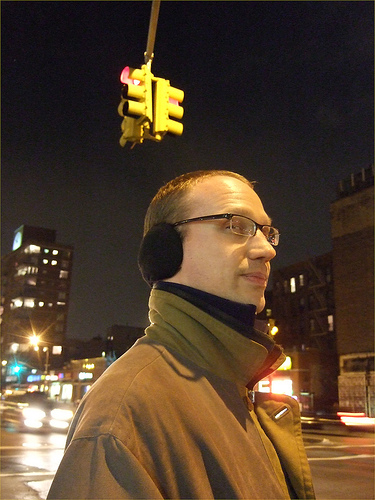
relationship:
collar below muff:
[153, 292, 267, 385] [139, 223, 184, 281]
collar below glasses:
[153, 292, 267, 385] [169, 214, 281, 248]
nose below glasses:
[250, 230, 275, 261] [169, 214, 281, 248]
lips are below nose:
[245, 267, 267, 286] [250, 230, 275, 261]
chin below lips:
[243, 292, 270, 311] [245, 267, 267, 286]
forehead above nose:
[193, 179, 271, 220] [250, 230, 275, 261]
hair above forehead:
[146, 171, 246, 225] [193, 179, 271, 220]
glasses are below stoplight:
[169, 214, 281, 248] [116, 72, 187, 148]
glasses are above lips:
[169, 214, 281, 248] [245, 267, 267, 286]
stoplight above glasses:
[116, 72, 187, 148] [169, 214, 281, 248]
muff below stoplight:
[139, 223, 184, 281] [116, 72, 187, 148]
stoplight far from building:
[116, 72, 187, 148] [1, 226, 72, 366]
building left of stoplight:
[1, 226, 72, 366] [116, 72, 187, 148]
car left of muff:
[1, 393, 73, 438] [139, 223, 184, 281]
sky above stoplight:
[3, 6, 374, 335] [116, 72, 187, 148]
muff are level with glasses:
[139, 223, 184, 281] [169, 214, 281, 248]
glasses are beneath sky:
[169, 214, 281, 248] [3, 6, 374, 335]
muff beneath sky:
[139, 223, 184, 281] [3, 6, 374, 335]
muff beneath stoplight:
[139, 223, 184, 281] [116, 72, 187, 148]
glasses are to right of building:
[169, 214, 281, 248] [1, 226, 72, 366]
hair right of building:
[146, 171, 246, 225] [1, 226, 72, 366]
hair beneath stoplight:
[146, 171, 246, 225] [116, 72, 187, 148]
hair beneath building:
[146, 171, 246, 225] [1, 226, 72, 366]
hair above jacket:
[146, 171, 246, 225] [45, 336, 313, 498]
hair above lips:
[146, 171, 246, 225] [245, 267, 267, 286]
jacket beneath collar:
[45, 336, 313, 498] [153, 292, 267, 385]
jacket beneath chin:
[45, 336, 313, 498] [243, 292, 270, 311]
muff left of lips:
[139, 223, 184, 281] [245, 267, 267, 286]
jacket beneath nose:
[45, 336, 313, 498] [250, 230, 275, 261]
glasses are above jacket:
[169, 214, 281, 248] [45, 336, 313, 498]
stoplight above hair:
[116, 72, 187, 148] [146, 171, 246, 225]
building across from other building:
[1, 226, 72, 366] [325, 192, 374, 416]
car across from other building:
[1, 393, 73, 438] [325, 192, 374, 416]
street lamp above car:
[31, 331, 54, 391] [1, 393, 73, 438]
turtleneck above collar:
[155, 281, 257, 335] [153, 292, 267, 385]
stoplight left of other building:
[116, 72, 187, 148] [325, 192, 374, 416]